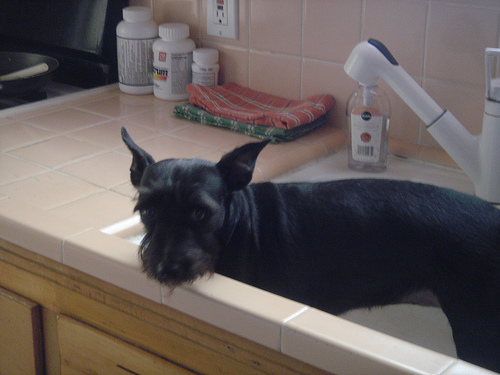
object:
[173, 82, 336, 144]
couple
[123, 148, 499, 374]
bath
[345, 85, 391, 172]
bottle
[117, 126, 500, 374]
dog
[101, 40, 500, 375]
sink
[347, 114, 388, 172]
soap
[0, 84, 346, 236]
counter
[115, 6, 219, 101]
bottles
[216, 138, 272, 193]
ear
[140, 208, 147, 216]
eye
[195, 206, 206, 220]
eye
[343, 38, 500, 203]
faucet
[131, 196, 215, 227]
straight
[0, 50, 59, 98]
pot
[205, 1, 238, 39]
plug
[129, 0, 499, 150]
wall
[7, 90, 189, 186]
tile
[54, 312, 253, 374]
cabinet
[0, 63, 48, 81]
utensil